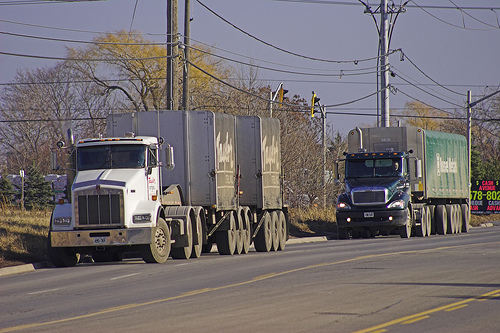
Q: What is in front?
A: Truck.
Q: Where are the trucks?
A: Road.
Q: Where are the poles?
A: Along road.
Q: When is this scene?
A: Afternoon.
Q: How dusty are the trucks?
A: Very dusty.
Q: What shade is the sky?
A: Blue.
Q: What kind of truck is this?
A: Semi truck.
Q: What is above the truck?
A: Power lines.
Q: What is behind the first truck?
A: Another truck.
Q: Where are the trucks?
A: Highway.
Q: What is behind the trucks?
A: Trees.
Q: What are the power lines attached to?
A: Poles.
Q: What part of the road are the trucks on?
A: Side.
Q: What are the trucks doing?
A: Parked.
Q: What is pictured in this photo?
A: Roadway with yellow pass and no pass lines.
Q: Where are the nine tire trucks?
A: Left side.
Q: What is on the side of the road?
A: Grass and trees.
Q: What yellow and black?
A: Two street signs.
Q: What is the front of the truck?
A: White and silver.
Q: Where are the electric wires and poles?
A: Above the trucks.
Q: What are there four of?
A: Lit up lights on the truck.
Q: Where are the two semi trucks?
A: On the road.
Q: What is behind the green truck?
A: Bulletin with neon words and numbers.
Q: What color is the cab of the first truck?
A: White.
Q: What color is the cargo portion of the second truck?
A: Green.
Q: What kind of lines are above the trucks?
A: Electric.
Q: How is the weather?
A: Sunny and clear.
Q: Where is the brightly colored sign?
A: Behind the trucks.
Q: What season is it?
A: Fall.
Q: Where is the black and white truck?
A: In the front.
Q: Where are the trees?
A: Behind the trucks.